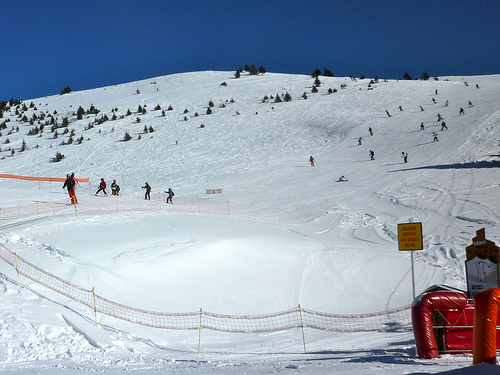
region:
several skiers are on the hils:
[51, 160, 182, 218]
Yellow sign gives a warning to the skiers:
[394, 216, 426, 264]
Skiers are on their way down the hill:
[270, 50, 482, 218]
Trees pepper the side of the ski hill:
[8, 71, 437, 156]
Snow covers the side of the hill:
[7, 6, 495, 370]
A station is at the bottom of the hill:
[410, 222, 497, 372]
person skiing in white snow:
[58, 160, 81, 210]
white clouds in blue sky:
[332, 10, 369, 35]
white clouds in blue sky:
[408, 14, 449, 41]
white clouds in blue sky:
[90, 8, 153, 52]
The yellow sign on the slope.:
[388, 217, 427, 299]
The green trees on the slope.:
[2, 94, 92, 156]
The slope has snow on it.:
[3, 79, 488, 371]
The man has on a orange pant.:
[64, 187, 84, 207]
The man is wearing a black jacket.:
[58, 179, 81, 191]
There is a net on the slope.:
[196, 307, 416, 357]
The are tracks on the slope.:
[382, 165, 470, 320]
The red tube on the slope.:
[414, 279, 459, 354]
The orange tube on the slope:
[470, 296, 498, 369]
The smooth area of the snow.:
[56, 203, 399, 320]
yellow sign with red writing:
[396, 220, 424, 253]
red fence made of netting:
[2, 240, 428, 360]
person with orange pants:
[60, 173, 77, 211]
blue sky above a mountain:
[1, 0, 499, 113]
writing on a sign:
[399, 223, 420, 249]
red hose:
[408, 290, 468, 361]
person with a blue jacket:
[163, 186, 175, 206]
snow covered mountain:
[2, 60, 499, 370]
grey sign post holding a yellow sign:
[407, 248, 418, 305]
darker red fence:
[2, 170, 91, 187]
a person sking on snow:
[50, 165, 86, 211]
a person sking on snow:
[92, 170, 114, 207]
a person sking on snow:
[101, 172, 126, 201]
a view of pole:
[392, 210, 439, 316]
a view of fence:
[201, 295, 268, 371]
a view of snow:
[196, 128, 275, 190]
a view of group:
[63, 145, 176, 242]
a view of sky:
[190, 43, 236, 66]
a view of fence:
[148, 282, 298, 374]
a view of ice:
[163, 206, 236, 271]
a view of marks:
[51, 310, 116, 360]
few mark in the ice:
[38, 316, 118, 363]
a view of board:
[395, 224, 459, 337]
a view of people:
[63, 140, 194, 227]